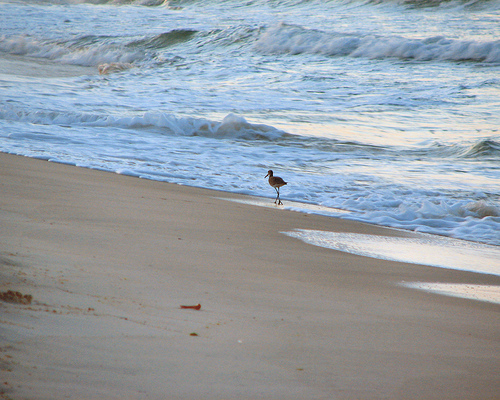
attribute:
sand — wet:
[339, 236, 394, 252]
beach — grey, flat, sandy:
[5, 145, 497, 398]